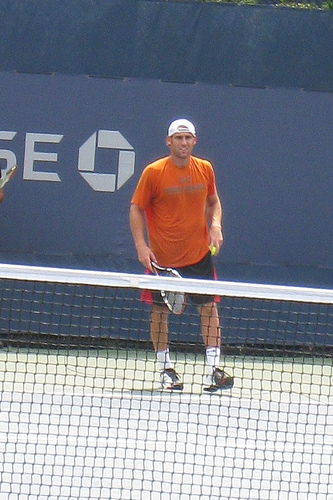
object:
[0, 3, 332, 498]
court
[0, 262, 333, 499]
net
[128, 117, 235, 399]
man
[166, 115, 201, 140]
cap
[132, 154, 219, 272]
t-shirt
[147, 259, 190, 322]
racket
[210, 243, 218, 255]
ball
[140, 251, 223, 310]
shorts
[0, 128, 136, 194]
logo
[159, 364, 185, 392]
sneaker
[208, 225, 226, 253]
hand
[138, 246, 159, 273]
hand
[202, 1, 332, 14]
tree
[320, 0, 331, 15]
leaves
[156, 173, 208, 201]
logo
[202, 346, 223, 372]
sock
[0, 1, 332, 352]
tarp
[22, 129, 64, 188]
e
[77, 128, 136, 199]
symbol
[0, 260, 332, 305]
strip